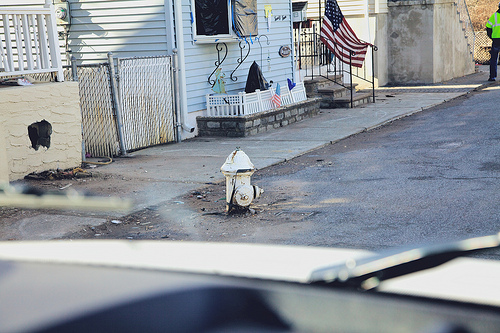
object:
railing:
[293, 17, 379, 108]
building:
[0, 2, 387, 182]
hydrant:
[219, 147, 264, 217]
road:
[87, 80, 500, 249]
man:
[484, 2, 500, 81]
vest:
[486, 12, 500, 39]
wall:
[0, 2, 475, 189]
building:
[381, 0, 477, 87]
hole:
[28, 118, 53, 151]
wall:
[0, 3, 393, 182]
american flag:
[318, 0, 369, 69]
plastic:
[195, 0, 229, 36]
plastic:
[233, 0, 258, 36]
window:
[190, 0, 232, 39]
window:
[229, 1, 260, 39]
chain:
[0, 56, 180, 157]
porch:
[295, 26, 378, 108]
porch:
[0, 53, 178, 158]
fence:
[0, 0, 65, 82]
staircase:
[304, 73, 374, 109]